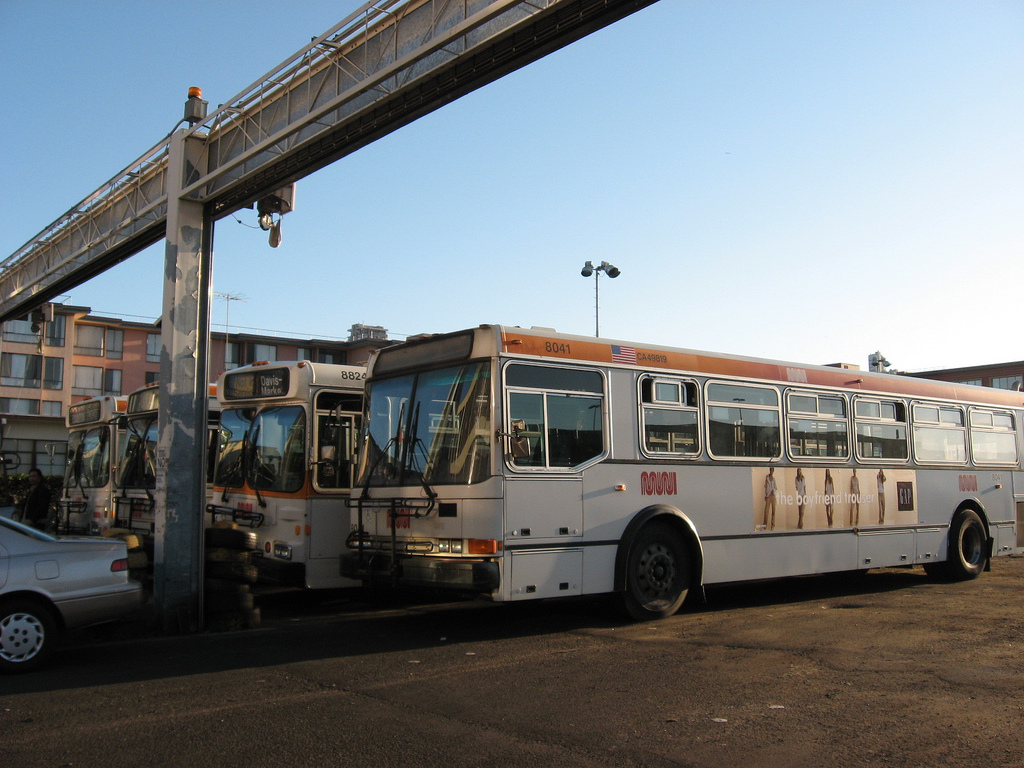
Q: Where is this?
A: This is at the road.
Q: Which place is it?
A: It is a road.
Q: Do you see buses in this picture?
A: Yes, there is a bus.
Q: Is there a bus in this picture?
A: Yes, there is a bus.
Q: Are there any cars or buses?
A: Yes, there is a bus.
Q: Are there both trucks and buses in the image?
A: No, there is a bus but no trucks.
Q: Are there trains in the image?
A: No, there are no trains.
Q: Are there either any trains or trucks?
A: No, there are no trains or trucks.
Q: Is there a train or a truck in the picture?
A: No, there are no trains or trucks.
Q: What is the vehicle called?
A: The vehicle is a bus.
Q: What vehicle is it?
A: The vehicle is a bus.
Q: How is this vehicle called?
A: That is a bus.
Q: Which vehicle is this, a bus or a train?
A: That is a bus.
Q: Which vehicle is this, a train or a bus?
A: That is a bus.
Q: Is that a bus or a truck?
A: That is a bus.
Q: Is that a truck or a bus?
A: That is a bus.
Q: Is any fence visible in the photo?
A: No, there are no fences.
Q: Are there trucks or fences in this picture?
A: No, there are no fences or trucks.